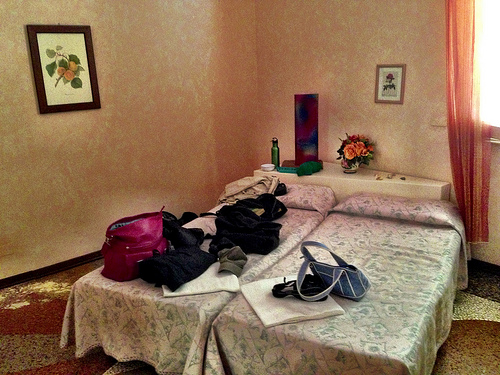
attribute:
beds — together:
[302, 206, 379, 255]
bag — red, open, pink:
[93, 206, 141, 289]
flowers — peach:
[42, 45, 89, 94]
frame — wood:
[80, 29, 100, 104]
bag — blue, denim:
[302, 237, 359, 293]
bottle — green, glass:
[264, 135, 289, 167]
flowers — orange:
[340, 139, 362, 152]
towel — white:
[254, 275, 292, 340]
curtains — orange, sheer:
[451, 5, 477, 187]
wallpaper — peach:
[129, 43, 210, 132]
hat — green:
[306, 161, 319, 179]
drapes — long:
[451, 153, 495, 243]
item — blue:
[273, 169, 298, 177]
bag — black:
[215, 217, 276, 243]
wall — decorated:
[331, 11, 383, 51]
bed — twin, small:
[387, 199, 447, 353]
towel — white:
[195, 278, 242, 301]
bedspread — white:
[387, 248, 437, 365]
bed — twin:
[290, 177, 308, 234]